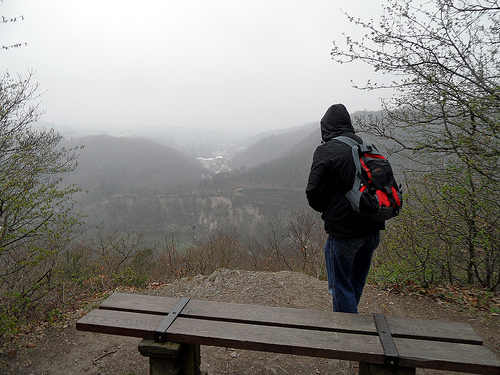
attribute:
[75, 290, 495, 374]
bench — wooden, wood plank, plank, wood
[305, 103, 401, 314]
person — looking, standing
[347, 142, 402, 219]
backpack — black, red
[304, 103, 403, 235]
jacket — black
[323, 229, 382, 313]
jeans — blue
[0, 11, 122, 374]
tree — bare, here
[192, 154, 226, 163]
water — here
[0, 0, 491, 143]
sky — foggy, hazy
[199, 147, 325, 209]
hillside — large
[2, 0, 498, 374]
day — cloudy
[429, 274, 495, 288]
leaf — brown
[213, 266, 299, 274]
edge — cement